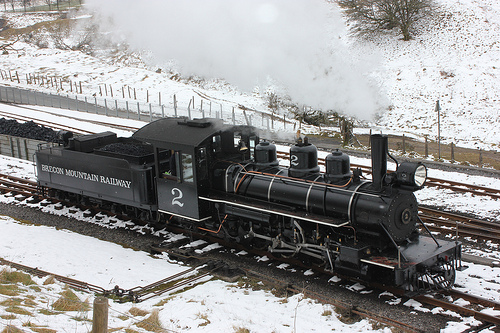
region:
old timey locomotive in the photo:
[36, 108, 466, 303]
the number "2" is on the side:
[155, 172, 197, 211]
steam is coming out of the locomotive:
[198, 20, 401, 144]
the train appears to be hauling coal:
[45, 130, 159, 185]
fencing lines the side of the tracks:
[12, 65, 194, 121]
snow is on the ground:
[4, 219, 116, 274]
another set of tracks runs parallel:
[436, 179, 498, 244]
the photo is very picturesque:
[3, 2, 498, 326]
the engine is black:
[121, 115, 455, 265]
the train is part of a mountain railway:
[37, 154, 145, 203]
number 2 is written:
[172, 193, 194, 215]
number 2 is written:
[173, 188, 188, 230]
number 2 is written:
[177, 194, 192, 200]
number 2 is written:
[173, 200, 183, 203]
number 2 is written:
[176, 187, 184, 205]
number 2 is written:
[165, 197, 186, 205]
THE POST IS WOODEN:
[90, 306, 109, 326]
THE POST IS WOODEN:
[101, 298, 104, 315]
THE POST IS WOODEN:
[90, 293, 110, 331]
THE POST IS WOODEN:
[102, 295, 111, 325]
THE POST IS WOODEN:
[99, 290, 108, 330]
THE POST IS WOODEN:
[97, 310, 126, 331]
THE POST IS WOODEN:
[82, 295, 127, 322]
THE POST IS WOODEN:
[93, 294, 114, 319]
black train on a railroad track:
[37, 80, 467, 301]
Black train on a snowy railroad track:
[32, 114, 464, 296]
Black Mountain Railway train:
[33, 88, 468, 300]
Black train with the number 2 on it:
[19, 70, 464, 305]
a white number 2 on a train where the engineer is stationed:
[166, 175, 185, 214]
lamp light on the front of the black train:
[397, 157, 428, 188]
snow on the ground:
[32, 234, 233, 321]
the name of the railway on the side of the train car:
[31, 156, 135, 190]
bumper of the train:
[394, 252, 475, 289]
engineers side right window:
[153, 145, 199, 182]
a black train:
[28, 121, 475, 294]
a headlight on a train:
[408, 158, 434, 194]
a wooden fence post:
[80, 288, 108, 330]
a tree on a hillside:
[341, 5, 451, 41]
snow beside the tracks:
[2, 220, 193, 305]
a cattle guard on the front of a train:
[391, 240, 472, 300]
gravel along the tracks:
[286, 261, 401, 328]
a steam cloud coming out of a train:
[75, 0, 390, 125]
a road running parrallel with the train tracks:
[3, 79, 159, 121]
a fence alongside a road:
[6, 85, 131, 117]